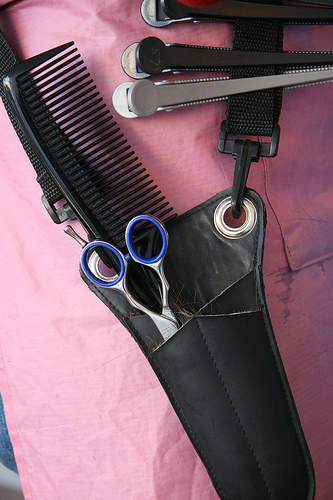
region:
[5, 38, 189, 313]
black hair comb in black pouch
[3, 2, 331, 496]
pink apron under hair dresser's tools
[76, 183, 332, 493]
black pouch containing scissors and combs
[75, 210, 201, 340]
pair of blue handled scissors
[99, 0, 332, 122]
two black and one silver hair clip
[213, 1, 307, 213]
nylon strap attached to black pouch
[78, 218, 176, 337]
Scissors in a black case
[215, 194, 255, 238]
A metal ring around a hole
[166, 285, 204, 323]
Hair inside a case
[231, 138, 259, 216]
A plastic clip attached to a ring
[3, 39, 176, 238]
A black comb in a black case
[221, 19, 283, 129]
A strap attached to a clip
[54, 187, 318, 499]
A black case with grooming tools inside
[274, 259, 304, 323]
A stain on a piece of cloth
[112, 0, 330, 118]
A row of clips on a cloth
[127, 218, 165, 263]
Blue ring around a scissor handle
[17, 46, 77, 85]
black tooth on comb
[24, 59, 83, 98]
black tooth on comb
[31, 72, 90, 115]
black tooth on comb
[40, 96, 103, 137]
black tooth on comb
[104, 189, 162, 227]
black tooth on comb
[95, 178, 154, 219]
black tooth on comb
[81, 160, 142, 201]
black tooth on comb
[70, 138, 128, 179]
black tooth on comb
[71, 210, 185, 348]
handles of scissors are blue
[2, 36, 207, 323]
the comb is color black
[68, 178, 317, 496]
a black container for scissors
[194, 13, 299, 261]
a black strap on a hole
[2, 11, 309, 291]
two black straps attached to holes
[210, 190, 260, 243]
a hole with silver border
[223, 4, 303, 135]
the strap color black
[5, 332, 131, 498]
a sheet color pink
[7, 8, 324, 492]
hair-styling tools on pink fabric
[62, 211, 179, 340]
silver scissors with blue handles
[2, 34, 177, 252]
black comb with even teeth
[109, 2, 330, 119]
silver and black hair clips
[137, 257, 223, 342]
loose hairs next to scissors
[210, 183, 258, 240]
plastic hook through silver ring of case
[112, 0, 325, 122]
long clips attached to black strap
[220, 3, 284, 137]
strap made of synthetic woven material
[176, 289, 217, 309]
snippets of hair in comb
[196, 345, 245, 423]
stitch in black holder